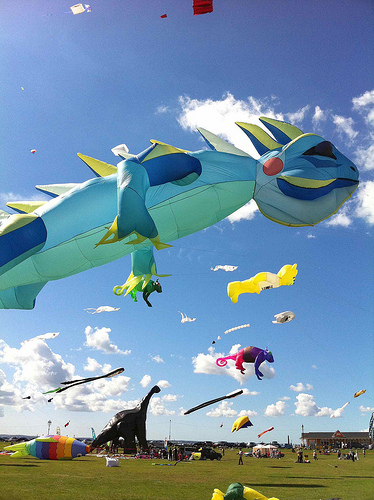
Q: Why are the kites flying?
A: It is windy.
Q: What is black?
A: The dinosaur.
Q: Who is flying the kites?
A: Men.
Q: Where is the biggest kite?
A: At the front of the picture.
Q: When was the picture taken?
A: Daytime.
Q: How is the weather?
A: Cloudy.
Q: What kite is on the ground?
A: The rainbow one.